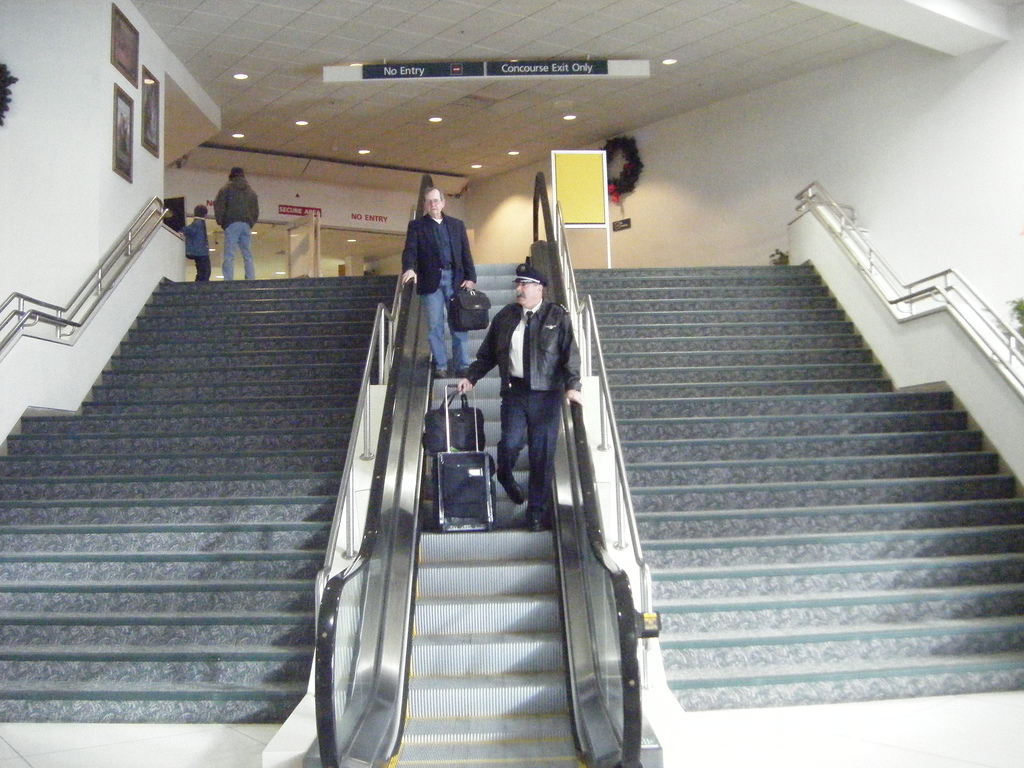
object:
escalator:
[314, 170, 662, 765]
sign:
[362, 60, 608, 79]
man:
[457, 263, 580, 532]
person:
[400, 187, 479, 378]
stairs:
[564, 263, 1024, 712]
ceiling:
[124, 2, 909, 186]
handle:
[444, 384, 479, 453]